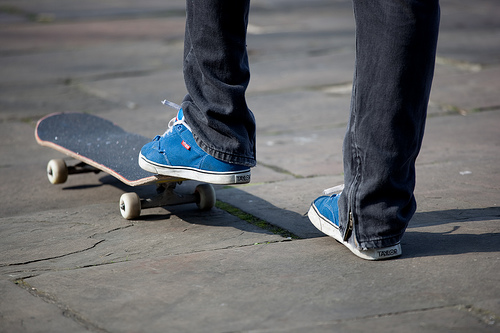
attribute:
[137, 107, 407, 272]
kicks — blue, suede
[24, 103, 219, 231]
skateboard — black, rough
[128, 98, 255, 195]
shoe — blue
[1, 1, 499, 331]
ground — tile, flaked, stone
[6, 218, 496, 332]
stone — large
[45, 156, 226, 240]
wheels — white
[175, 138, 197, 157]
tag — red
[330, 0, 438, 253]
jean leg — blue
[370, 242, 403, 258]
taylor — black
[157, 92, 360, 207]
laces — white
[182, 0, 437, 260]
jeans — black